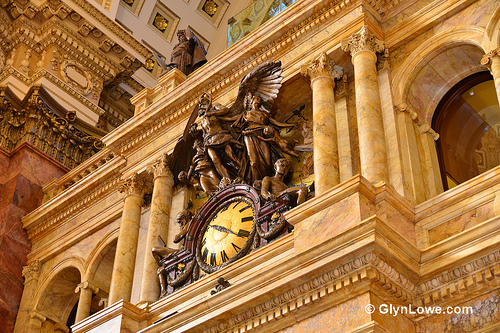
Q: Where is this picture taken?
A: Inside of a building.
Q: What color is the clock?
A: Brown and yellow.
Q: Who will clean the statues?
A: The building workers.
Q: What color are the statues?
A: Brown.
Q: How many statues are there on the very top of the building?
A: One.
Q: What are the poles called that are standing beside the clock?
A: Pillars.